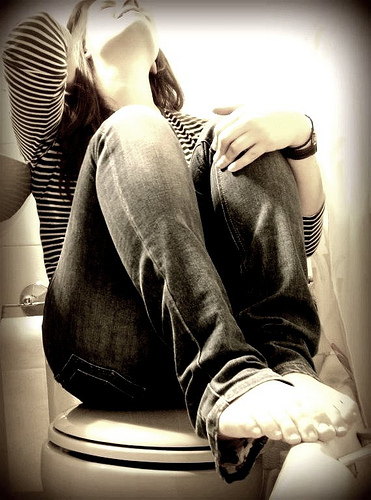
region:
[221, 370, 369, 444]
A pair of feet.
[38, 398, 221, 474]
A toilet seat in black and white.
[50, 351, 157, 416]
The pocket of some jeans.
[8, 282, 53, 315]
The left knob of a towel rack.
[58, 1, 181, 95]
The face of a smiling woman.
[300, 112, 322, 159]
A small bracelet on her wrist.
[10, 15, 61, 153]
A shirt sleeve with a striped pattern.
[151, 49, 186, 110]
A lock of brown hair.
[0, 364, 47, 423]
Tile wall behind the toilet.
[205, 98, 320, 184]
A hand over a knee.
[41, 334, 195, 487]
the toilet is white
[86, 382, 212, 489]
the toilet is white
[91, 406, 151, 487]
the toilet is white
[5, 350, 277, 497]
the toilet is white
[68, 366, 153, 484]
the toilet is white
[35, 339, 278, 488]
the toilet is white and visible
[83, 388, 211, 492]
the toilet is white and visible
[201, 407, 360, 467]
womans toes are visible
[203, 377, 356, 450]
womans toes are visible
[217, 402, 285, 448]
womans toes are visible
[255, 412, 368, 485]
womans toes are visible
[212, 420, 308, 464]
womans toes are visible